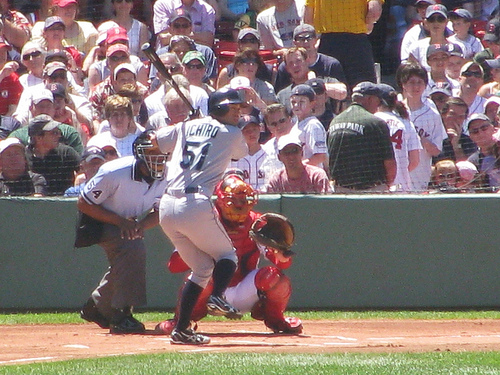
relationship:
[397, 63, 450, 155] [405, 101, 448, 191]
fan wearing jersey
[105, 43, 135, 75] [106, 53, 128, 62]
man wearing sunglasses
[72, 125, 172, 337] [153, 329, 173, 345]
umpire behind plate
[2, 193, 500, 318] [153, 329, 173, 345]
wall behind plate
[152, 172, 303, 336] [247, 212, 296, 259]
catcher has baseball glove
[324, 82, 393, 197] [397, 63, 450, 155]
fan looking at fan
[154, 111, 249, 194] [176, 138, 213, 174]
jersey has number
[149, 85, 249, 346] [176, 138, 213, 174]
baseball player has number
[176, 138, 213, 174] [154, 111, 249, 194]
number sewn onto jersey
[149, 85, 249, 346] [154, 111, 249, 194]
baseball player wearing jersey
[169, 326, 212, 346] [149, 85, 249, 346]
sneaker worn by baseball player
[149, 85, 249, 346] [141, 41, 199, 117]
baseball player holding bat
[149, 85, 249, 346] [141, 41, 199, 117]
baseball player swinging bat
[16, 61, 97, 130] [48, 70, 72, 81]
man wearing sunglasses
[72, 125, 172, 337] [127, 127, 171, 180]
umpire has mask